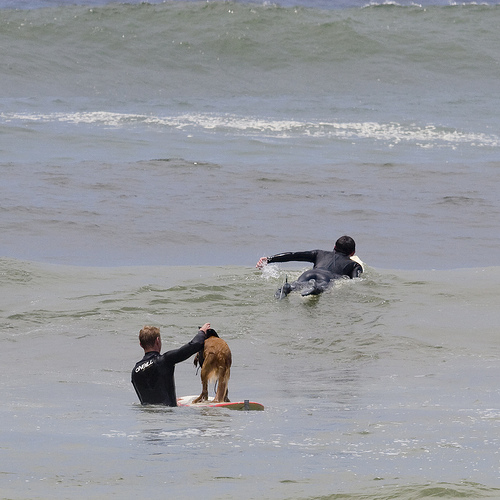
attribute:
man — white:
[131, 322, 210, 409]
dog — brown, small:
[194, 328, 232, 405]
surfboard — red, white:
[178, 395, 265, 412]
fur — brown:
[195, 337, 231, 404]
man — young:
[256, 236, 364, 299]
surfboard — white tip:
[351, 254, 365, 270]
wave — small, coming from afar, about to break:
[4, 110, 500, 151]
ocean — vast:
[2, 2, 498, 499]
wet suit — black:
[131, 330, 205, 407]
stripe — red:
[210, 401, 264, 409]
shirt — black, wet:
[267, 251, 362, 279]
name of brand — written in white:
[135, 357, 156, 372]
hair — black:
[333, 236, 355, 255]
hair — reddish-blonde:
[139, 326, 160, 348]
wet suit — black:
[268, 251, 362, 295]